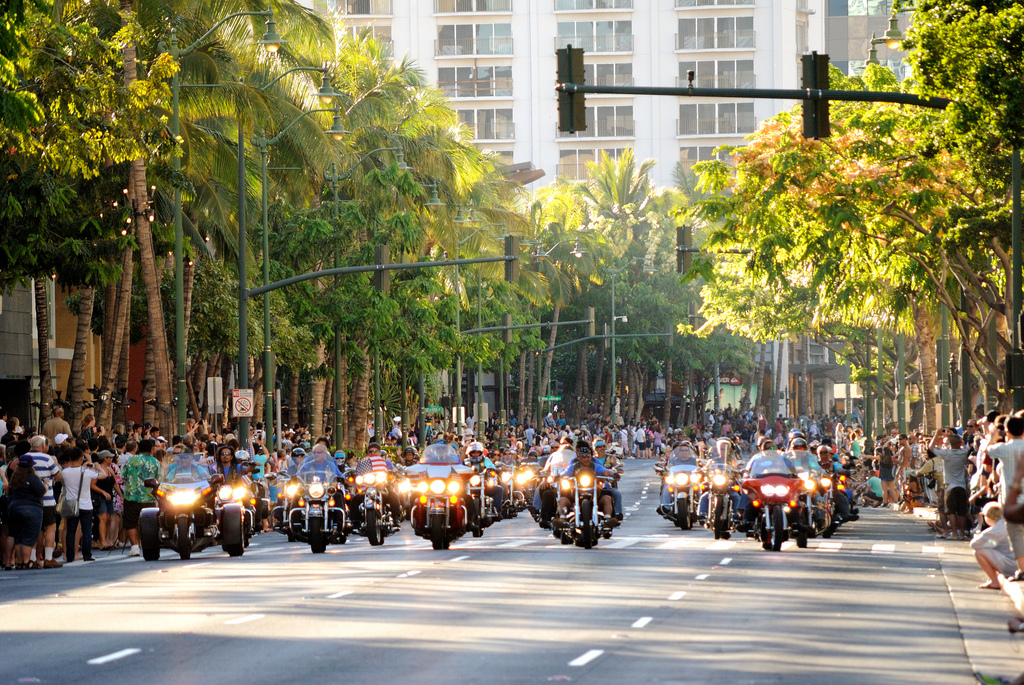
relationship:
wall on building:
[635, 6, 678, 183] [121, 285, 344, 419]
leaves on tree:
[691, 151, 730, 196] [675, 95, 1021, 420]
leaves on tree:
[661, 197, 716, 232] [673, 99, 1021, 350]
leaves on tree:
[831, 292, 876, 337] [708, 90, 1017, 376]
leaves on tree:
[868, 245, 925, 293] [695, 125, 1020, 387]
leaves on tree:
[723, 301, 810, 346] [21, 6, 160, 372]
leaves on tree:
[828, 346, 861, 375] [312, 75, 403, 423]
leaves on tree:
[385, 197, 436, 265] [178, 80, 263, 413]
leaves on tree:
[442, 138, 503, 203] [304, 79, 397, 440]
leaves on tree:
[582, 138, 621, 200] [550, 168, 689, 430]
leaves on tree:
[484, 276, 523, 319] [410, 201, 497, 403]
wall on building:
[508, 4, 560, 183] [405, 10, 741, 140]